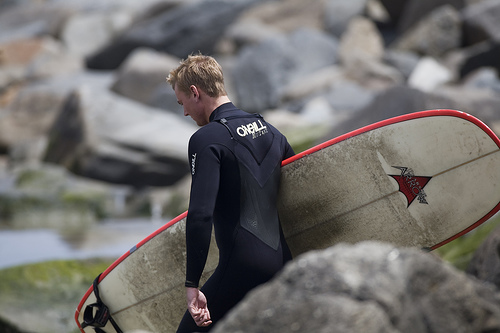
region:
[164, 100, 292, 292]
the swimsuit is black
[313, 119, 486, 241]
the surf board has red arrow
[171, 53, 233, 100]
the hair is brown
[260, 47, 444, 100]
the background is blurr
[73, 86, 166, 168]
the rocks are huge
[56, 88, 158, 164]
the rocks are grey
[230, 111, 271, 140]
writing is on the back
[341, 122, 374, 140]
the frame is red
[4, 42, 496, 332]
the scene is daylight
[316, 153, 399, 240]
the surfboard has dirt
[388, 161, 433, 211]
Logo on a surfboard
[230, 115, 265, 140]
Logo on a wet suit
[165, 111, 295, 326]
Wet suit worn by surfer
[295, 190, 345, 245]
Dirt and wear on a surfboard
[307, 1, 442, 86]
Large boulders in the background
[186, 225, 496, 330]
Large boulder in the foreground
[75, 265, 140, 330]
Strap on a surfboard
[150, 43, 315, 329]
Surfer carrying surfboard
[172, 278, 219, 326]
Left hand of the surfer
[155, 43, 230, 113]
Short haircut on a surfer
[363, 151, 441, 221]
logo on the surfboard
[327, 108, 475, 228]
red and white board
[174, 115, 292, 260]
wetsuit on the man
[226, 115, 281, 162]
name on the back of the suit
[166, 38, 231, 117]
blonde hair on the man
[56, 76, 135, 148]
blurry background of the photo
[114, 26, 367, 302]
man walking towards the water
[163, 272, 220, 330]
hand of the man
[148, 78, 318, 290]
black wetsuit on man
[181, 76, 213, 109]
ear on the man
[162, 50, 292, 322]
White man wearing black body swim suit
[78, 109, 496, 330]
Red and white dirty surfboard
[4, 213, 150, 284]
blurry water area that may be part of river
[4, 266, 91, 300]
green grass on ground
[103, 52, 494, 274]
Man carrying a dirty surfboard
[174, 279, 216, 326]
curled pinkish white hand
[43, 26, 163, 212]
A bunch of rocks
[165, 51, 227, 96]
dirty blonde hair on head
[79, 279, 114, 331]
Black rope on surfboard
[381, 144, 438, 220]
Arrow brand marked on surfboard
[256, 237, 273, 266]
part of a costume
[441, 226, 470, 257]
part of an edge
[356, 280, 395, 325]
parrt of a rock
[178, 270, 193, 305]
part of a seeve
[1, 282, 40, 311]
part of a ground